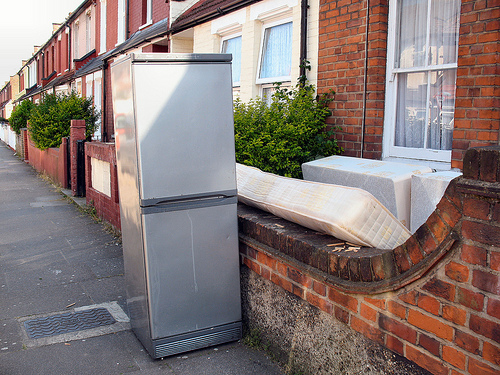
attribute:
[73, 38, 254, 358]
refrigerator — shaded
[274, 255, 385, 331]
wall — brick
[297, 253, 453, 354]
wall — brick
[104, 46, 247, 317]
appliance — Old , stainless , steel 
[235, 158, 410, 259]
mattress — Old , leaning, white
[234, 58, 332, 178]
green plants — Green 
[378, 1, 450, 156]
windows — white , wooden 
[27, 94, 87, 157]
planter — Arched , stone , area 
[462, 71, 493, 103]
bricks — Red , brown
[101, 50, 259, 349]
refrigerator — steel, old, silver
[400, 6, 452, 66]
curtains — closed, white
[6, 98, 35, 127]
bush — green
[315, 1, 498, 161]
building — brick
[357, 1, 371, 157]
pipe — gray, black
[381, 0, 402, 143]
frame — white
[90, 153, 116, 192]
grate — metal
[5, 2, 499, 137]
houses — brick, white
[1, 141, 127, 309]
pavement — black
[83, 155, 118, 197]
plate — metal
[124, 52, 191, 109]
corner — sunny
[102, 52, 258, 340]
freezer — silver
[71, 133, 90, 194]
gate — black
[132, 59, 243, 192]
door — utility